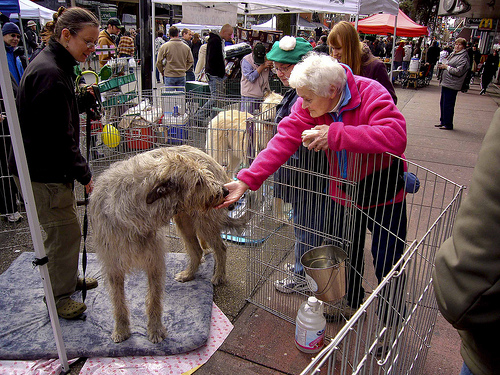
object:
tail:
[215, 192, 257, 236]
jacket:
[6, 37, 93, 186]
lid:
[307, 296, 318, 307]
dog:
[85, 143, 232, 345]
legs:
[144, 260, 165, 345]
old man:
[213, 50, 409, 317]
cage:
[0, 92, 466, 374]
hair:
[285, 50, 348, 100]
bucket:
[299, 244, 348, 302]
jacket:
[235, 63, 410, 210]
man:
[156, 25, 194, 92]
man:
[194, 23, 234, 126]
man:
[0, 20, 24, 100]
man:
[94, 15, 123, 69]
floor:
[1, 303, 241, 373]